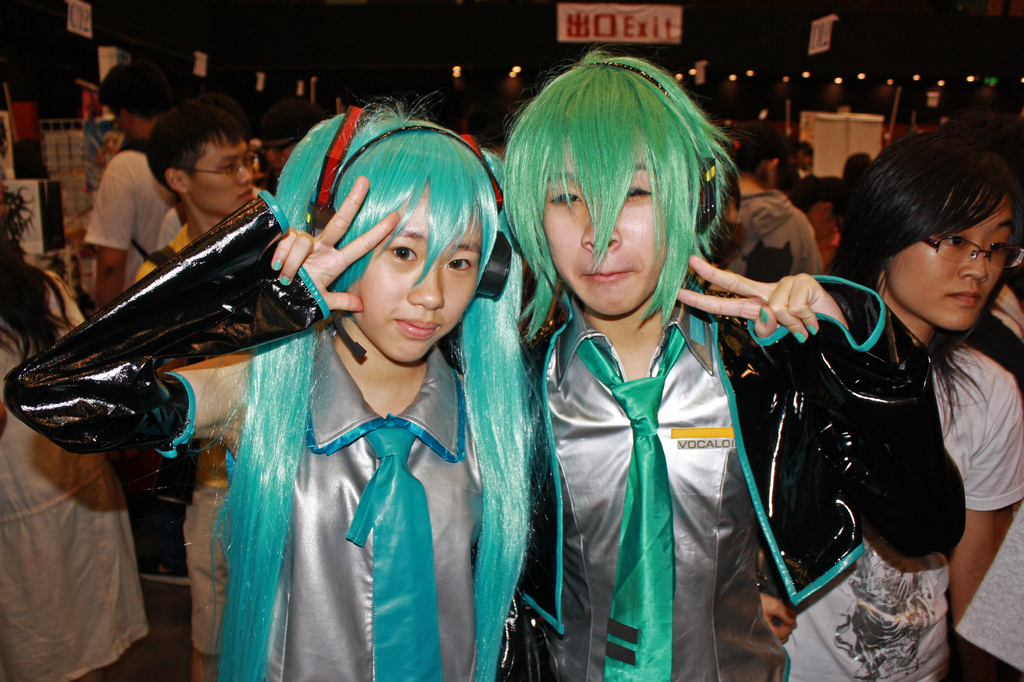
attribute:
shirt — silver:
[521, 314, 779, 667]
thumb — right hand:
[299, 286, 380, 321]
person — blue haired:
[37, 96, 537, 645]